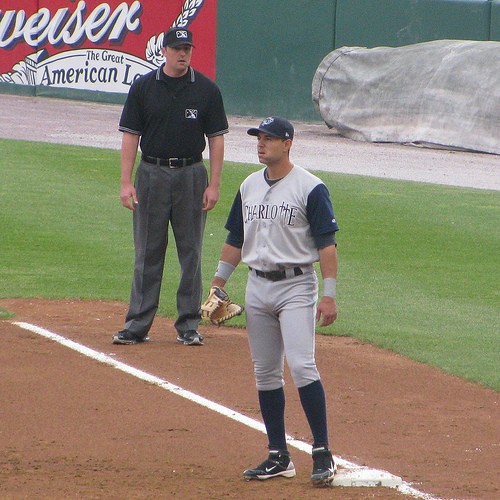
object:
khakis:
[122, 152, 210, 337]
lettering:
[243, 200, 298, 227]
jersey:
[223, 162, 339, 270]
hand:
[206, 280, 228, 302]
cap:
[162, 26, 197, 49]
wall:
[228, 4, 316, 114]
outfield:
[0, 95, 499, 298]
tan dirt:
[20, 337, 103, 412]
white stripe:
[12, 322, 442, 499]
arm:
[303, 181, 336, 297]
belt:
[249, 265, 312, 282]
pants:
[244, 264, 319, 392]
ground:
[330, 131, 500, 200]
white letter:
[107, 0, 143, 44]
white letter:
[83, 1, 111, 44]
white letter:
[59, 0, 89, 49]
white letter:
[21, 7, 52, 49]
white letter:
[0, 8, 28, 47]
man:
[207, 116, 339, 487]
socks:
[297, 378, 329, 448]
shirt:
[117, 61, 230, 160]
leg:
[245, 311, 285, 449]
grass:
[0, 131, 499, 389]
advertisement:
[0, 0, 217, 94]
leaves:
[346, 268, 387, 297]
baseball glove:
[200, 285, 245, 325]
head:
[255, 115, 294, 164]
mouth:
[257, 149, 267, 159]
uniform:
[223, 163, 338, 391]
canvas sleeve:
[311, 38, 499, 154]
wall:
[0, 0, 118, 94]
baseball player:
[207, 115, 337, 485]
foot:
[309, 445, 336, 486]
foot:
[240, 445, 296, 481]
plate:
[332, 466, 403, 489]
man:
[111, 27, 229, 348]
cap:
[247, 115, 294, 140]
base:
[332, 466, 404, 493]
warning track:
[1, 94, 499, 189]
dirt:
[335, 458, 365, 471]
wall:
[341, 1, 484, 43]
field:
[0, 136, 499, 499]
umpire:
[110, 26, 229, 346]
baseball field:
[1, 1, 499, 499]